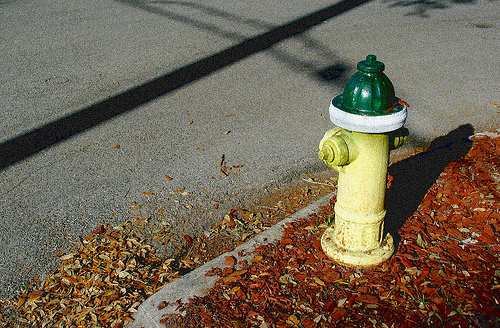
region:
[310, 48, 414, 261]
green and yellow fire hydrant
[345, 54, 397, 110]
green top on fire hydrant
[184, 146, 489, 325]
mulch surrounding fire hydrant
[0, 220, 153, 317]
some mulch on street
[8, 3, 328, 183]
shadows on street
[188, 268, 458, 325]
brown mulch next to fire hydrant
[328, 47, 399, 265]
fire hydrant is green, yellow and white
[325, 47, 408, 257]
fire hydrant next to street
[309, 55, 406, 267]
fire hydrant on brown mulch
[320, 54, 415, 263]
green, yellow and white hydrant on brown mulch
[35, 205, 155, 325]
pile of leaves on pavement beside side walk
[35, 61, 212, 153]
shadow of electric pole being cast on road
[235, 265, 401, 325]
sidewalk covered in leaves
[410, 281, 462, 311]
green grass growing on sidewalk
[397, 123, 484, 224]
shadow of fire hydrant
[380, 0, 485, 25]
shadow of tree on pavement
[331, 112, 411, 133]
white trim of fire hydrant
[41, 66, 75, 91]
circular crack in pavement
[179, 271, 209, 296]
concrete sidewalk barrier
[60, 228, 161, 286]
pile of leaves on pavement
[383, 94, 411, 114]
small leaves on top of fire hydrant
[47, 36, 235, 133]
shadow of electric pole on pavement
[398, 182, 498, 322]
side walk covered in leaves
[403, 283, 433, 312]
small sprig of green grass beside road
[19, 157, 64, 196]
crack on surface of pavement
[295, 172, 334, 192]
small stick laying on road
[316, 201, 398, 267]
base of hydrant covered in dirt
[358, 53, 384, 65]
green bolt on top of hyrdrant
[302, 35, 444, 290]
a fire hydrant on sidewalk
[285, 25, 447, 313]
a yellow and green fire hydrant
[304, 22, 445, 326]
a yellow and green hydrant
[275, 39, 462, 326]
a fire hydrant in the leaves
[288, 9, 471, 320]
a hydrant on the sidewalk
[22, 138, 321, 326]
leaves on the ground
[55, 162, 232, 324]
leaves on the street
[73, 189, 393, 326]
leaves on the side of the street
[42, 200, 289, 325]
leaves on the road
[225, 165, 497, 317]
leaves on the ground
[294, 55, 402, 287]
fire hydrant on road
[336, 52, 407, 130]
green top of fire hydrant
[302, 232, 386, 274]
bottom of fire hydrant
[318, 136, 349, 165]
side of fire hydrant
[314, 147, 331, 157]
bolt on side of fire hydrant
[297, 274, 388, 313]
mulch in flower bed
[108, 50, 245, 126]
shadow in middle of road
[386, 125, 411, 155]
bolt on side of hydrant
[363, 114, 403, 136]
white border of hydrant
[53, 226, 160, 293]
leaves along side of sidewalk